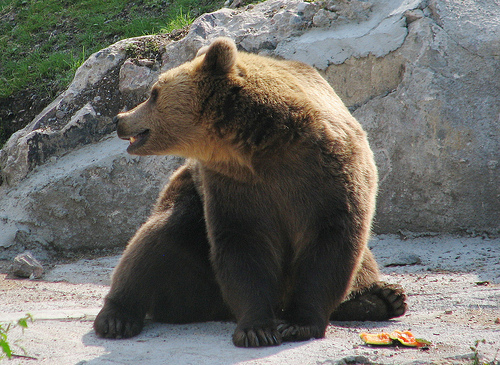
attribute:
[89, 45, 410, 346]
bear — brown, large, sitting, looking, sittig, o rock, sit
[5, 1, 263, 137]
grass — green, small patch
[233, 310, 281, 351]
claw — dark brown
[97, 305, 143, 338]
claw — dark brown, foot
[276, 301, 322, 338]
claw — dark brown, padded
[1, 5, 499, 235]
rock — large, lighter shade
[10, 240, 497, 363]
ground — cement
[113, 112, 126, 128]
nose — black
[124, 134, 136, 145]
tooth — canine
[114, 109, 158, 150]
mouth — open